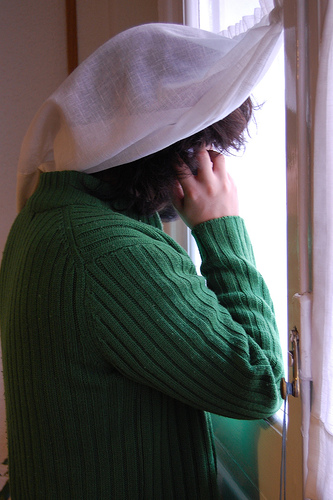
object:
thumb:
[166, 180, 187, 212]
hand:
[167, 148, 234, 226]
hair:
[96, 92, 251, 212]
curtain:
[19, 25, 274, 171]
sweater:
[0, 178, 280, 500]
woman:
[0, 23, 280, 500]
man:
[0, 23, 281, 500]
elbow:
[238, 323, 280, 422]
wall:
[0, 1, 67, 258]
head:
[68, 24, 252, 207]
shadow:
[216, 417, 254, 480]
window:
[189, 0, 286, 405]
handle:
[279, 323, 300, 407]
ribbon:
[280, 401, 285, 499]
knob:
[279, 379, 289, 400]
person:
[3, 24, 280, 500]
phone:
[184, 143, 196, 173]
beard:
[158, 202, 181, 221]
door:
[283, 1, 316, 499]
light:
[262, 27, 284, 272]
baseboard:
[218, 468, 248, 499]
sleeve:
[197, 220, 281, 418]